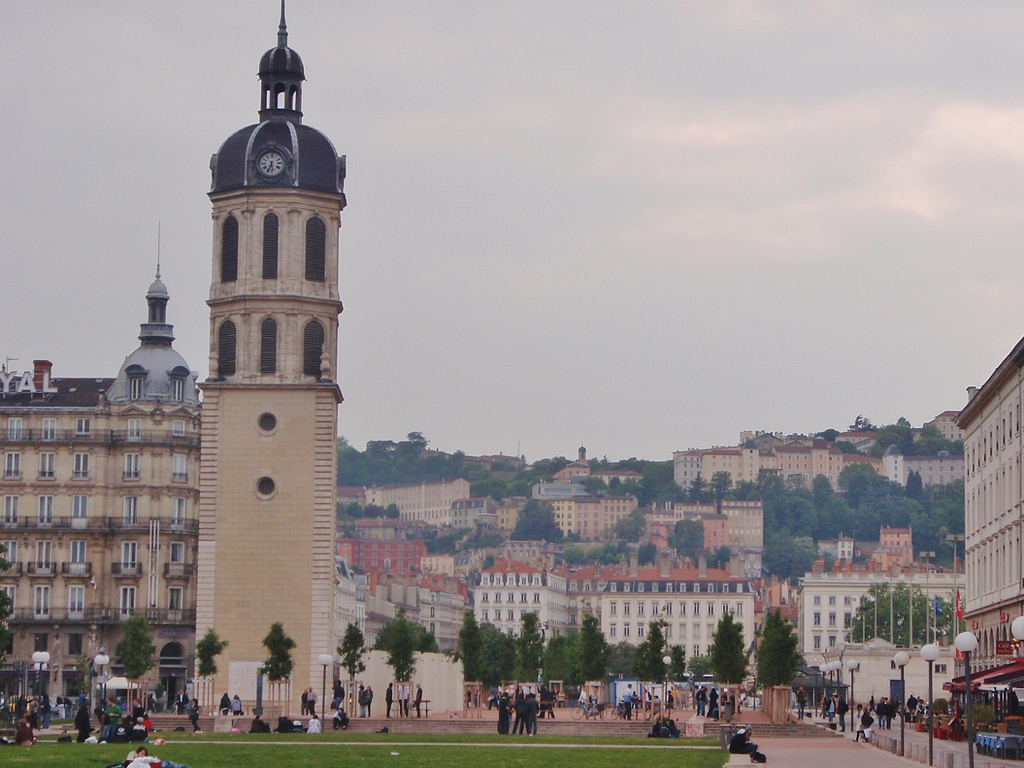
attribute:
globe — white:
[910, 632, 949, 667]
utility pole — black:
[918, 656, 942, 765]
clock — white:
[253, 144, 295, 183]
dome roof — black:
[203, 112, 353, 203]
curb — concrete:
[720, 747, 759, 765]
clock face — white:
[259, 153, 283, 177]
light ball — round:
[956, 622, 974, 648]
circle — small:
[256, 408, 278, 428]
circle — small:
[246, 471, 283, 500]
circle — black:
[252, 408, 279, 432]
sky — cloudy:
[1, 8, 1021, 464]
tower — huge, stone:
[181, 13, 348, 735]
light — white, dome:
[895, 644, 1017, 699]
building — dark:
[558, 547, 844, 697]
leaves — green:
[226, 599, 324, 682]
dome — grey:
[74, 270, 319, 448]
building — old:
[945, 363, 1021, 642]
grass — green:
[241, 711, 704, 764]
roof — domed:
[197, 102, 401, 301]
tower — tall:
[130, 41, 385, 670]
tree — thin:
[321, 605, 391, 683]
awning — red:
[939, 644, 1020, 711]